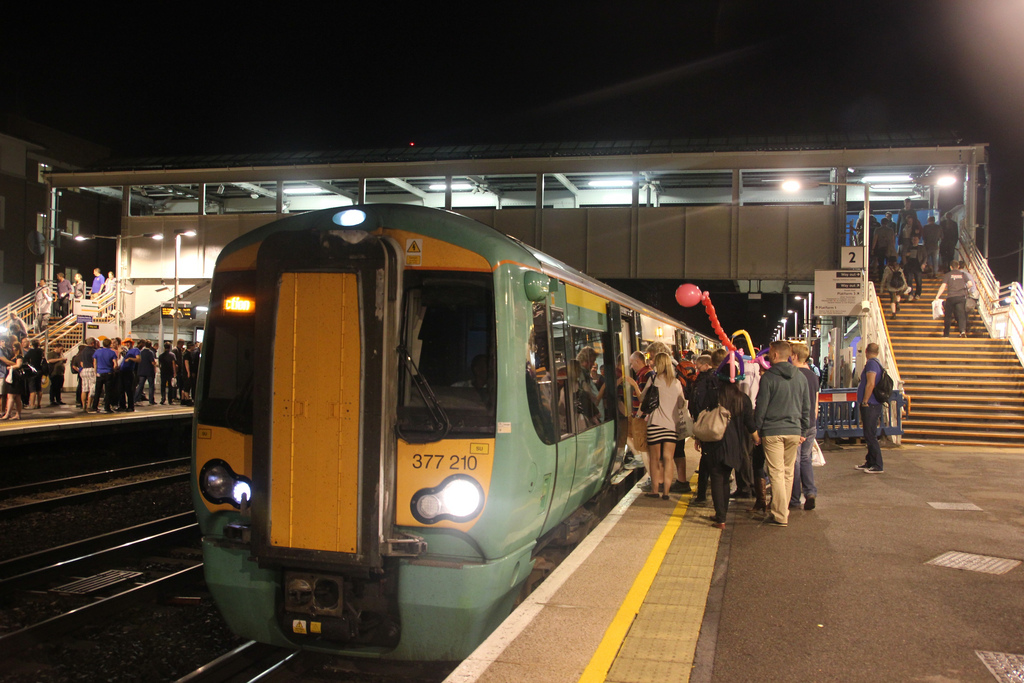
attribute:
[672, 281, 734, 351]
balloon — red, helium-filled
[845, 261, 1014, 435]
stairway — wide